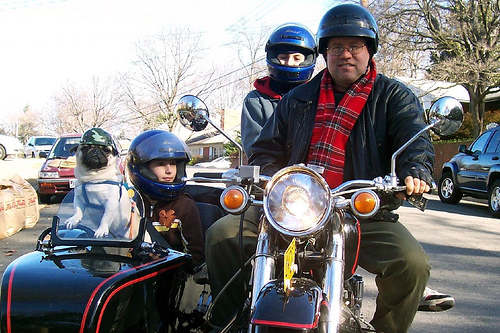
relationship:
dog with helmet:
[63, 127, 140, 240] [77, 129, 116, 149]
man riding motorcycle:
[204, 4, 433, 333] [172, 93, 466, 333]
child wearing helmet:
[126, 129, 206, 318] [127, 128, 191, 199]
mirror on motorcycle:
[426, 95, 464, 138] [172, 93, 466, 333]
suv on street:
[437, 128, 499, 218] [439, 215, 499, 290]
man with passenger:
[204, 4, 433, 333] [240, 22, 317, 161]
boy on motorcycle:
[240, 22, 317, 161] [172, 93, 466, 333]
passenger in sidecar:
[126, 129, 206, 318] [2, 241, 192, 333]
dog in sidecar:
[63, 127, 140, 240] [2, 241, 192, 333]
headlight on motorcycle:
[262, 164, 333, 237] [172, 93, 466, 333]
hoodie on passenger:
[253, 77, 281, 101] [240, 22, 317, 161]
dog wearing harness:
[63, 127, 140, 240] [80, 180, 126, 211]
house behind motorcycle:
[397, 76, 499, 132] [172, 93, 466, 333]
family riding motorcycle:
[127, 3, 451, 333] [172, 93, 466, 333]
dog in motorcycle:
[63, 127, 140, 240] [172, 93, 466, 333]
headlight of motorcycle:
[262, 164, 333, 237] [172, 93, 466, 333]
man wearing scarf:
[204, 4, 433, 333] [304, 59, 377, 189]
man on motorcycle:
[204, 4, 433, 333] [172, 93, 466, 333]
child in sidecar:
[126, 129, 206, 318] [2, 241, 192, 333]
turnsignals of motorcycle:
[219, 184, 381, 219] [172, 93, 466, 333]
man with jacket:
[204, 4, 433, 333] [247, 71, 438, 221]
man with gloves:
[204, 4, 433, 333] [399, 164, 436, 186]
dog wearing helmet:
[63, 127, 140, 240] [77, 129, 116, 149]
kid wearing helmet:
[126, 129, 206, 318] [127, 128, 191, 199]